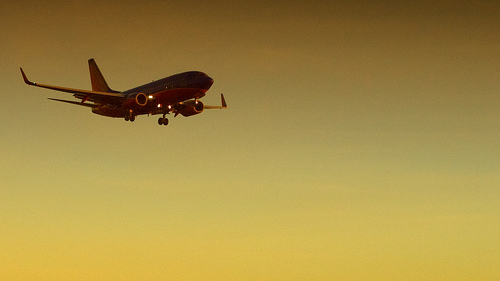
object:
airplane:
[20, 58, 228, 127]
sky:
[0, 0, 500, 281]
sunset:
[0, 152, 497, 280]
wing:
[19, 67, 126, 107]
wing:
[205, 93, 228, 110]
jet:
[135, 92, 148, 106]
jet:
[179, 99, 204, 118]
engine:
[122, 92, 148, 110]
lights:
[148, 95, 154, 99]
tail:
[87, 58, 111, 93]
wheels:
[158, 117, 169, 125]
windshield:
[200, 73, 206, 76]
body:
[90, 70, 214, 119]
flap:
[47, 98, 98, 108]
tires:
[119, 108, 136, 122]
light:
[33, 81, 36, 84]